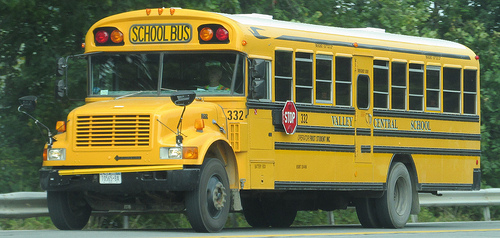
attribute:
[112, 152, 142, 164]
arrow — black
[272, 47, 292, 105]
window — dark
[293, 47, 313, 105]
window — dark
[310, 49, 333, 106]
window — dark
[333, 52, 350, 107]
window — dark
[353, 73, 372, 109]
window — dark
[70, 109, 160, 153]
lines — grill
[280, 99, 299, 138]
stop sign — red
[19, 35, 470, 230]
bus — school, yellow, black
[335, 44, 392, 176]
door — emergency exit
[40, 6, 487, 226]
bus — yellow